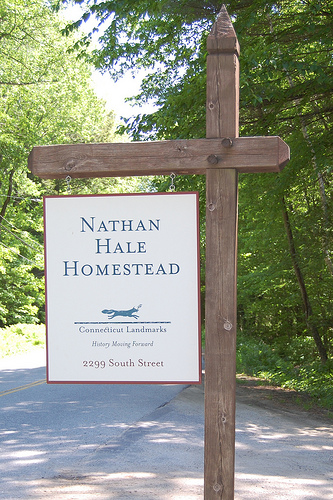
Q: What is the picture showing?
A: It is showing a road.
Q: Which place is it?
A: It is a road.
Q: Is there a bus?
A: No, there are no buses.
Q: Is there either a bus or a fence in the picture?
A: No, there are no buses or fences.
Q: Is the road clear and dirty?
A: Yes, the road is clear and dirty.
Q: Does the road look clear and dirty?
A: Yes, the road is clear and dirty.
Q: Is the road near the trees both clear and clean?
A: No, the road is clear but dirty.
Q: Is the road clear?
A: Yes, the road is clear.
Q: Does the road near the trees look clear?
A: Yes, the road is clear.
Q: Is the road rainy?
A: No, the road is clear.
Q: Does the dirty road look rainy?
A: No, the road is clear.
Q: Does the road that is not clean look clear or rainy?
A: The road is clear.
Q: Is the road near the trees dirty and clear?
A: Yes, the road is dirty and clear.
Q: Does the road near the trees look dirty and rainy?
A: No, the road is dirty but clear.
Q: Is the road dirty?
A: Yes, the road is dirty.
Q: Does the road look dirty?
A: Yes, the road is dirty.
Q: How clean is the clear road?
A: The road is dirty.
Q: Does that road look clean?
A: No, the road is dirty.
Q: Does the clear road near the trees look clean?
A: No, the road is dirty.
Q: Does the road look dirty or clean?
A: The road is dirty.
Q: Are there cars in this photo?
A: No, there are no cars.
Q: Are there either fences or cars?
A: No, there are no cars or fences.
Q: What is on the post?
A: The sign is on the post.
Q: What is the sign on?
A: The sign is on the post.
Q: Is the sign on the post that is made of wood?
A: Yes, the sign is on the post.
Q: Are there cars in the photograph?
A: No, there are no cars.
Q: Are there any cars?
A: No, there are no cars.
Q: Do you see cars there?
A: No, there are no cars.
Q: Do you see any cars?
A: No, there are no cars.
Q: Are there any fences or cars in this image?
A: No, there are no cars or fences.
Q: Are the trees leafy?
A: Yes, the trees are leafy.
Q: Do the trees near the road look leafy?
A: Yes, the trees are leafy.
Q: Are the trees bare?
A: No, the trees are leafy.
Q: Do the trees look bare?
A: No, the trees are leafy.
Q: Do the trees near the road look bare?
A: No, the trees are leafy.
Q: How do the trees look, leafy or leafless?
A: The trees are leafy.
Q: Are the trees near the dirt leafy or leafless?
A: The trees are leafy.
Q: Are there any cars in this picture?
A: No, there are no cars.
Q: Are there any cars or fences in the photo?
A: No, there are no cars or fences.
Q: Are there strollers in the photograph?
A: No, there are no strollers.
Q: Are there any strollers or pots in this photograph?
A: No, there are no strollers or pots.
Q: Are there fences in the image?
A: No, there are no fences.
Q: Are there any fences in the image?
A: No, there are no fences.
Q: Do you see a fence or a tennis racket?
A: No, there are no fences or rackets.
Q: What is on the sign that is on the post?
A: The logo is on the sign.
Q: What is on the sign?
A: The logo is on the sign.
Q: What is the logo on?
A: The logo is on the sign.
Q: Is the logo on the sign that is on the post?
A: Yes, the logo is on the sign.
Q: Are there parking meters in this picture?
A: No, there are no parking meters.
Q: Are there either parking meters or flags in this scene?
A: No, there are no parking meters or flags.